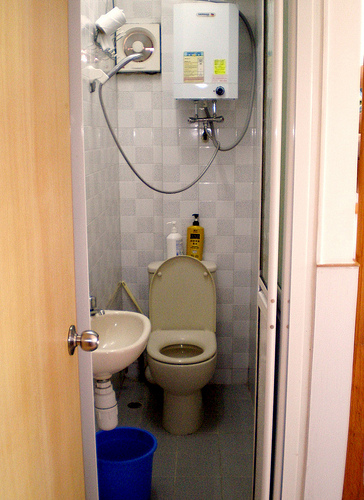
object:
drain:
[123, 397, 144, 413]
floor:
[163, 438, 258, 500]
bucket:
[92, 419, 160, 500]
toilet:
[144, 248, 221, 438]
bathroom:
[73, 0, 295, 500]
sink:
[79, 303, 152, 435]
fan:
[108, 20, 162, 80]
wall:
[115, 12, 262, 260]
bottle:
[184, 211, 207, 261]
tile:
[120, 94, 172, 160]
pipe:
[91, 371, 125, 436]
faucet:
[83, 283, 109, 321]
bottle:
[164, 215, 186, 270]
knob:
[67, 319, 100, 362]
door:
[0, 0, 100, 500]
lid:
[145, 251, 226, 338]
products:
[161, 208, 210, 264]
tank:
[145, 256, 217, 304]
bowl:
[146, 329, 219, 397]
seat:
[146, 330, 217, 367]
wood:
[0, 0, 65, 500]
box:
[167, 0, 246, 108]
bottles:
[162, 211, 207, 264]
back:
[146, 260, 218, 275]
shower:
[86, 10, 121, 66]